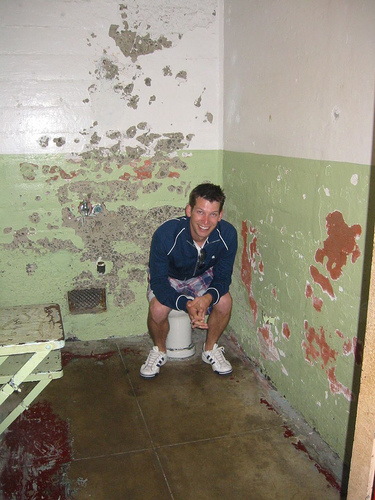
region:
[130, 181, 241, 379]
this is a man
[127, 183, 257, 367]
the man is using the toilet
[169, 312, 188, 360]
the sink is white in color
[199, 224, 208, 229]
the man is smiling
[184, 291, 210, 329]
the hands are folded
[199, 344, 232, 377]
the shoe is white in color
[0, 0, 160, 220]
the wall is old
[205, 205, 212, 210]
the man is light skinned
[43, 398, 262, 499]
the floor is dirty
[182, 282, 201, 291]
the man is wearing shorts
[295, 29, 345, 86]
part of a white wall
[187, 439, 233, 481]
part of the floor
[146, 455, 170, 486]
part of a line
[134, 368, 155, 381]
front of a shoe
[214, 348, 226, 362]
laces of a shoe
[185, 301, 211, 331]
part of some hands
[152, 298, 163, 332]
part of a knee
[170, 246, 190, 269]
part of a jacket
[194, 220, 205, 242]
chin of a man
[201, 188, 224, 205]
hair of a man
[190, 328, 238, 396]
tennis shoes are white and blue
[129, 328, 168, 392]
tennis shoes are white and blue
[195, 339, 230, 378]
tennis shoes are white and blue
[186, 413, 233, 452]
part of a floor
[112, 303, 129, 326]
part of a wall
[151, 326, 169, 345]
part of a right leg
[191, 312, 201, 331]
part of a some fingers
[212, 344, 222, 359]
laces of a shoe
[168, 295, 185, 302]
sleeve of a jumper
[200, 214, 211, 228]
nose of a man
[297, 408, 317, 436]
edge of a wall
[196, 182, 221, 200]
hair of a man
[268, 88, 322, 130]
part of a wall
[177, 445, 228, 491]
part of a floor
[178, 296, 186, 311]
sleeve of a jumper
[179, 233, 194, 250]
collar of a jumper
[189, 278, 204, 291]
part of a short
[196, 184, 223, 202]
hair of a guy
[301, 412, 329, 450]
edge of a wall